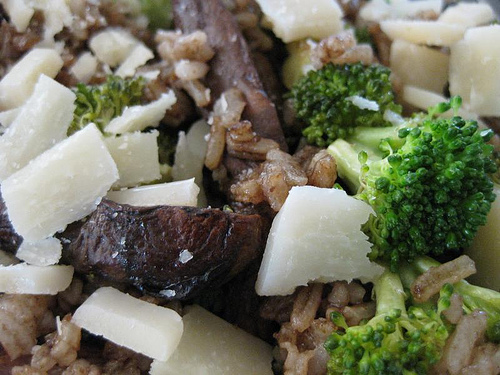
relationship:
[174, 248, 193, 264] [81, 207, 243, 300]
spot on mushroom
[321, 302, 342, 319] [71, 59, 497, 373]
hair on broccolli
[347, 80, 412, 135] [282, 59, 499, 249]
flecks on broccolli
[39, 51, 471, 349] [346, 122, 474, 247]
dish contains vegetable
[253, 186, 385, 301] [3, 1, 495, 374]
vegetable in dish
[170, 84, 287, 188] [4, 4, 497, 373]
rice and vegetables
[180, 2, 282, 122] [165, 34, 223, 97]
meat covered in rice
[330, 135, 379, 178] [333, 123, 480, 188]
stem on broccoli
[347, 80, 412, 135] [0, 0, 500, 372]
flecks in stir fry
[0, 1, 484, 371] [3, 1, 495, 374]
food sauteing in dish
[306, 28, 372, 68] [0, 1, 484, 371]
rice sauteing in food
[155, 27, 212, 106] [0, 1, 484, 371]
rice sauteing in food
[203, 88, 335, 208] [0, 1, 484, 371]
rice sauteing in food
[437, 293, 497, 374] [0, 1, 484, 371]
rice sauteing in food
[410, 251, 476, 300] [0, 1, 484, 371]
rice sauteing in food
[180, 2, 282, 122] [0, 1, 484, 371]
meat sliced in food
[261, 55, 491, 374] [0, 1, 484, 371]
broccoli cooked in food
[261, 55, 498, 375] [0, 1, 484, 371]
broccoli cooked in food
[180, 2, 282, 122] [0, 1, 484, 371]
meat cooked in food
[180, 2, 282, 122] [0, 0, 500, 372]
meat cooked in stir fry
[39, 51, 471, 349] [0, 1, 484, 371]
dish cooked in food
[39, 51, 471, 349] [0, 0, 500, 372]
dish cooked in stir fry